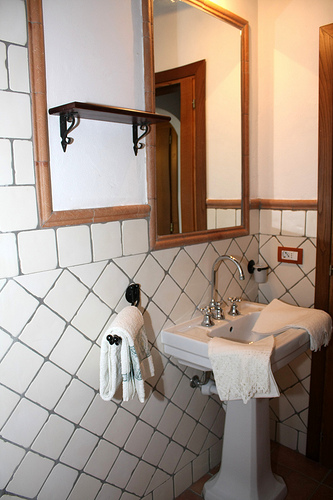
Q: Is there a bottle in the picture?
A: No, there are no bottles.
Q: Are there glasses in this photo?
A: No, there are no glasses.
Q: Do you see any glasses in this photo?
A: No, there are no glasses.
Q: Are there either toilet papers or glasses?
A: No, there are no glasses or toilet papers.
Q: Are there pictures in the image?
A: No, there are no pictures.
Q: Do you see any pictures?
A: No, there are no pictures.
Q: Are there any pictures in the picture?
A: No, there are no pictures.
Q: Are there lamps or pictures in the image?
A: No, there are no pictures or lamps.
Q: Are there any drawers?
A: No, there are no drawers.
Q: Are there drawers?
A: No, there are no drawers.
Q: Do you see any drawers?
A: No, there are no drawers.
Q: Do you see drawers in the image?
A: No, there are no drawers.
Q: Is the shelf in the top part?
A: Yes, the shelf is in the top of the image.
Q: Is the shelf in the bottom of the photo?
A: No, the shelf is in the top of the image.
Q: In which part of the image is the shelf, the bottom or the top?
A: The shelf is in the top of the image.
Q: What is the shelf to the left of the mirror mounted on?
A: The shelf is mounted on the wall.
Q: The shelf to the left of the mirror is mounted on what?
A: The shelf is mounted on the wall.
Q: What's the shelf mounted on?
A: The shelf is mounted on the wall.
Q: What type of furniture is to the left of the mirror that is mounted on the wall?
A: The piece of furniture is a shelf.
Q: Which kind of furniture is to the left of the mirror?
A: The piece of furniture is a shelf.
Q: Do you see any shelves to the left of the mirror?
A: Yes, there is a shelf to the left of the mirror.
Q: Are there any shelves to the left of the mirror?
A: Yes, there is a shelf to the left of the mirror.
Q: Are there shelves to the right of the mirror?
A: No, the shelf is to the left of the mirror.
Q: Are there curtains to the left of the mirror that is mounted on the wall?
A: No, there is a shelf to the left of the mirror.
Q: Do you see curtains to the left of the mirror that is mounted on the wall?
A: No, there is a shelf to the left of the mirror.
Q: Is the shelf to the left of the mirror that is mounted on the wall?
A: Yes, the shelf is to the left of the mirror.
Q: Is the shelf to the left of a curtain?
A: No, the shelf is to the left of the mirror.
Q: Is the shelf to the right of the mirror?
A: No, the shelf is to the left of the mirror.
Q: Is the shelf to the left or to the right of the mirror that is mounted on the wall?
A: The shelf is to the left of the mirror.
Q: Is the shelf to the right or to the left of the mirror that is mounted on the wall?
A: The shelf is to the left of the mirror.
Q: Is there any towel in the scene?
A: Yes, there is a towel.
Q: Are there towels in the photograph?
A: Yes, there is a towel.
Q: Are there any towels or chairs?
A: Yes, there is a towel.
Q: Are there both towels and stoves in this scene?
A: No, there is a towel but no stoves.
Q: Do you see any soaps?
A: No, there are no soaps.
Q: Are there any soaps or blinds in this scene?
A: No, there are no soaps or blinds.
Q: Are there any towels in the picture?
A: Yes, there is a towel.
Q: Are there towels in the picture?
A: Yes, there is a towel.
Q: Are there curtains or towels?
A: Yes, there is a towel.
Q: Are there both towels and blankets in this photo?
A: No, there is a towel but no blankets.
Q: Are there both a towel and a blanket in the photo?
A: No, there is a towel but no blankets.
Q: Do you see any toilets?
A: No, there are no toilets.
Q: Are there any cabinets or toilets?
A: No, there are no toilets or cabinets.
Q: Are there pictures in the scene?
A: No, there are no pictures.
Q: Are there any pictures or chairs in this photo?
A: No, there are no pictures or chairs.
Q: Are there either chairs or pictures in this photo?
A: No, there are no pictures or chairs.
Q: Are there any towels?
A: Yes, there is a towel.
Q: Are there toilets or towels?
A: Yes, there is a towel.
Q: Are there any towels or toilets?
A: Yes, there is a towel.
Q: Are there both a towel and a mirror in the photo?
A: Yes, there are both a towel and a mirror.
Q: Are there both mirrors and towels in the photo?
A: Yes, there are both a towel and a mirror.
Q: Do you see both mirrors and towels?
A: Yes, there are both a towel and a mirror.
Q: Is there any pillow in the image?
A: No, there are no pillows.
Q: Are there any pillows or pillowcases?
A: No, there are no pillows or pillowcases.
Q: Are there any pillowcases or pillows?
A: No, there are no pillows or pillowcases.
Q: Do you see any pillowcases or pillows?
A: No, there are no pillows or pillowcases.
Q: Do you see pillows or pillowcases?
A: No, there are no pillows or pillowcases.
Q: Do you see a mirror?
A: Yes, there is a mirror.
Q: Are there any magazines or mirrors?
A: Yes, there is a mirror.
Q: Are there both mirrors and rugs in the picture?
A: No, there is a mirror but no rugs.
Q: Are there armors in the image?
A: No, there are no armors.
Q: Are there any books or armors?
A: No, there are no armors or books.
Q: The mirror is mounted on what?
A: The mirror is mounted on the wall.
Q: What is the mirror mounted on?
A: The mirror is mounted on the wall.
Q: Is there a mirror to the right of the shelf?
A: Yes, there is a mirror to the right of the shelf.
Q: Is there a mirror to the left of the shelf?
A: No, the mirror is to the right of the shelf.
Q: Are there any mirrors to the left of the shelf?
A: No, the mirror is to the right of the shelf.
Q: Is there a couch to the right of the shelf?
A: No, there is a mirror to the right of the shelf.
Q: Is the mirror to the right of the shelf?
A: Yes, the mirror is to the right of the shelf.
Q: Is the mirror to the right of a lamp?
A: No, the mirror is to the right of the shelf.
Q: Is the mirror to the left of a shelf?
A: No, the mirror is to the right of a shelf.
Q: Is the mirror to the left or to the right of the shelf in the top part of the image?
A: The mirror is to the right of the shelf.